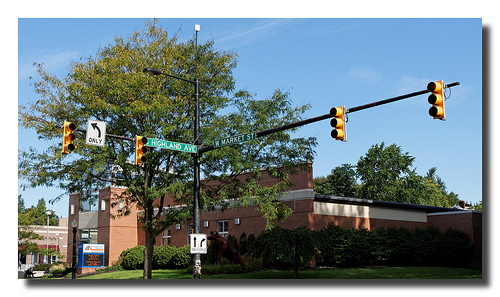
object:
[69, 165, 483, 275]
building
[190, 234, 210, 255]
sign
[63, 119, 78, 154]
traffic light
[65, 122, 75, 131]
stop light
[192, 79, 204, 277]
pole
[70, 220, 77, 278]
street-lamp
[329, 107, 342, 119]
light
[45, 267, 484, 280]
green grass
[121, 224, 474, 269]
shrub line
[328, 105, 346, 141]
traffic signal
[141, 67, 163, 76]
street light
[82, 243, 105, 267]
sign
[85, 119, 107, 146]
sign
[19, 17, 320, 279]
trees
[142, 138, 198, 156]
street sign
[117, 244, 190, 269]
bushes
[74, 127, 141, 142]
pole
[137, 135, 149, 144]
stop light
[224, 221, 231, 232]
window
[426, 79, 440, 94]
light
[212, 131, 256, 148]
sign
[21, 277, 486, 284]
ground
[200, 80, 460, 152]
pole